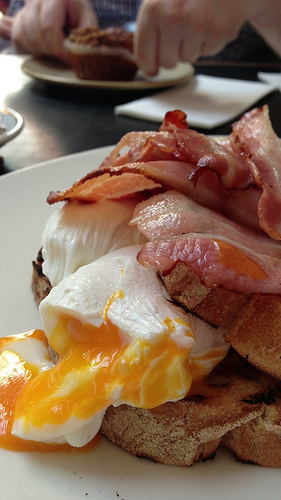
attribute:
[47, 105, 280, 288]
bacon — sliced up, lightly cooked, piece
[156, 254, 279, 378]
bread — toasted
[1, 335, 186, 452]
yolk — spilling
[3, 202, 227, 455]
egg — poached, white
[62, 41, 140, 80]
wrapper — being peeled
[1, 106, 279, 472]
sandwich — bacon, egg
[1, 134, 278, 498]
plate — white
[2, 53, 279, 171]
table — black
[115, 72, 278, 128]
napkin — white